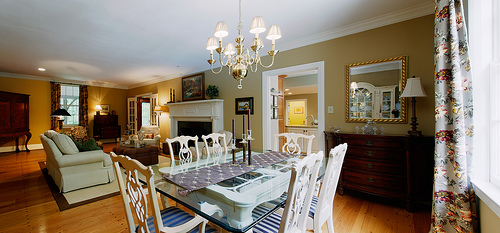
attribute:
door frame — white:
[275, 68, 320, 145]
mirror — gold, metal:
[348, 60, 398, 118]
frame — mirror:
[344, 55, 409, 125]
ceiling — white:
[3, 3, 183, 90]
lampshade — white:
[399, 77, 426, 98]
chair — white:
[109, 150, 199, 231]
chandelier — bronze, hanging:
[198, 11, 290, 90]